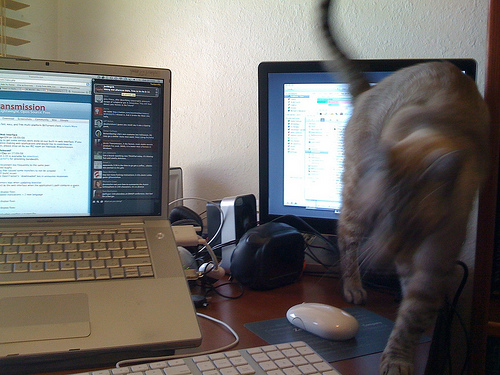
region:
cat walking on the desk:
[314, 10, 489, 357]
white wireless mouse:
[283, 294, 355, 337]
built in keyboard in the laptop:
[2, 223, 154, 283]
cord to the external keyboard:
[106, 304, 248, 360]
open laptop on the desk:
[0, 50, 205, 358]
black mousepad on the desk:
[244, 296, 406, 368]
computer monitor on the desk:
[259, 59, 470, 284]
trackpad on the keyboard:
[2, 293, 89, 343]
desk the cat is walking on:
[175, 244, 441, 373]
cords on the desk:
[177, 199, 474, 326]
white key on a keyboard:
[312, 357, 330, 374]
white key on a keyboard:
[300, 349, 324, 366]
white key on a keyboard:
[295, 342, 315, 358]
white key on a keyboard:
[289, 337, 306, 348]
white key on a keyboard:
[274, 339, 292, 352]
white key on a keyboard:
[260, 340, 280, 355]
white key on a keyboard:
[244, 344, 264, 355]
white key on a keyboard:
[222, 348, 242, 359]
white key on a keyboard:
[207, 349, 226, 361]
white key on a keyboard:
[190, 349, 210, 366]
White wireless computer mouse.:
[288, 303, 360, 340]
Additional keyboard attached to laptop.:
[93, 338, 343, 373]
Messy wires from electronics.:
[172, 204, 239, 297]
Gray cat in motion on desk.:
[311, 4, 497, 371]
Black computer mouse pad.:
[239, 303, 394, 361]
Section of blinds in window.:
[2, 0, 35, 60]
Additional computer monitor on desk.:
[250, 58, 475, 232]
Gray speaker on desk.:
[205, 194, 256, 266]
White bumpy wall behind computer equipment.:
[157, 5, 307, 54]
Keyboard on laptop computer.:
[0, 227, 157, 287]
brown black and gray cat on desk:
[306, 0, 496, 374]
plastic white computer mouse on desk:
[282, 297, 364, 342]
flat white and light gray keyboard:
[6, 337, 355, 374]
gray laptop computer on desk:
[1, 52, 208, 367]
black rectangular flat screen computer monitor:
[246, 52, 482, 241]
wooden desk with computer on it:
[1, 256, 446, 373]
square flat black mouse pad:
[237, 299, 437, 364]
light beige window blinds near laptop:
[0, 0, 35, 72]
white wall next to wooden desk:
[1, 0, 491, 374]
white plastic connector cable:
[167, 220, 226, 281]